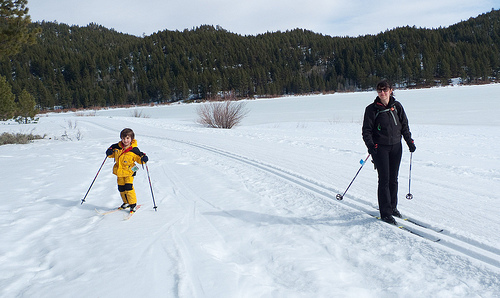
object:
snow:
[386, 279, 475, 290]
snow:
[181, 241, 382, 290]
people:
[103, 80, 416, 225]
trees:
[9, 12, 483, 91]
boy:
[104, 128, 147, 212]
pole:
[141, 161, 159, 206]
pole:
[403, 144, 419, 203]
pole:
[330, 149, 373, 203]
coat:
[104, 140, 148, 206]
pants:
[115, 173, 135, 207]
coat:
[360, 96, 415, 215]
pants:
[373, 147, 401, 218]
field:
[2, 88, 497, 296]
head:
[375, 81, 393, 100]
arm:
[400, 101, 416, 152]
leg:
[375, 156, 396, 223]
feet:
[375, 210, 399, 228]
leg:
[388, 151, 398, 211]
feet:
[386, 202, 404, 217]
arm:
[104, 142, 121, 161]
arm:
[132, 144, 149, 165]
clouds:
[321, 7, 363, 25]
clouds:
[121, 4, 138, 13]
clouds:
[218, 2, 351, 42]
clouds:
[403, 12, 479, 37]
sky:
[6, 1, 105, 30]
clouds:
[99, 3, 146, 13]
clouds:
[80, 3, 102, 15]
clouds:
[24, 3, 66, 24]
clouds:
[343, 13, 380, 37]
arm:
[361, 104, 380, 148]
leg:
[123, 173, 137, 207]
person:
[336, 81, 419, 225]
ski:
[320, 133, 383, 242]